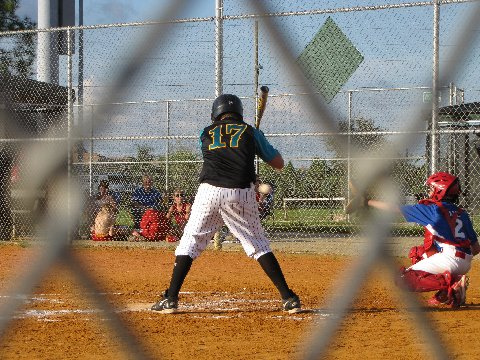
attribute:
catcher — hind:
[344, 170, 479, 313]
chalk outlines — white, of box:
[0, 282, 341, 323]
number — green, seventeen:
[204, 121, 248, 151]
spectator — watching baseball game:
[165, 183, 195, 240]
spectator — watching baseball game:
[120, 166, 168, 232]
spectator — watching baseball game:
[81, 171, 119, 219]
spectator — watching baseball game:
[82, 196, 125, 240]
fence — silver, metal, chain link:
[1, 5, 195, 170]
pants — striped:
[175, 183, 272, 253]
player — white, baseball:
[387, 170, 478, 307]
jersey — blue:
[400, 202, 477, 250]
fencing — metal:
[0, 0, 479, 257]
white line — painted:
[1, 290, 334, 321]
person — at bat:
[137, 81, 309, 325]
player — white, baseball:
[149, 95, 301, 311]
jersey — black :
[200, 121, 257, 187]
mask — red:
[402, 169, 465, 204]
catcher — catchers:
[401, 172, 471, 307]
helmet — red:
[419, 171, 462, 207]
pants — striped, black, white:
[173, 179, 273, 260]